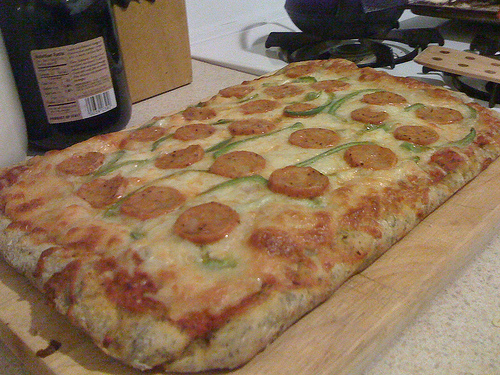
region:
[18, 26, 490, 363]
tasty pizza on board.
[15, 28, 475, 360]
delicious pizza ready to eat.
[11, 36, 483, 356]
flavorful pizza ready to eat.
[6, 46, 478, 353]
large pizza ready for consumption.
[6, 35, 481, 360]
delightful pizza ready to eat.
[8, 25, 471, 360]
full size pizza on board.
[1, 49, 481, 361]
full size delicious pizza.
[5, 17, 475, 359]
tasty pizza all ready to eat.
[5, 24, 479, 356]
big cheesy pizza ready for eating.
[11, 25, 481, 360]
big flavorful pizza for eating.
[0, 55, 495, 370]
A deep dish delicious looking homemade pizza.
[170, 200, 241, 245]
One piece of pepperoni on the pizza.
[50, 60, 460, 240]
Twenty three delicious pieces of pepperoni.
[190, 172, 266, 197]
One piece of green pepper.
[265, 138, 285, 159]
The cheese laying on the pizza.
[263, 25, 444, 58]
Cooking fire from the stove top.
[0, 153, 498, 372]
Piece of wood underneath the deep dish pizza.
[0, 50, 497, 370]
A beautiful beige counter top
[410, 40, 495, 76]
A spatula with six holes in it.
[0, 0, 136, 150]
A bottle of liquid used for cooking.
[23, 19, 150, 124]
brown bottle of sauce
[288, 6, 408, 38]
black pan on oven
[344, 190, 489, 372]
tan wooden board on counter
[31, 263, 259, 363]
brown and tan pizza with cheese and meat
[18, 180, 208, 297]
brown and tan pizza with cheese and meat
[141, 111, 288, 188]
brown and tan pizza with cheese and meat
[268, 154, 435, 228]
brown and tan pizza with cheese and meat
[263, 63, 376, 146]
brown and tan pizza with cheese and meat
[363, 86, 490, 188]
brown and tan pizza with cheese and meat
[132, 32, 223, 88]
tan wooden block on counter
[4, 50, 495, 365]
Rectangular pizza with green peppers and sausage.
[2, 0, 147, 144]
Dark wine bottle.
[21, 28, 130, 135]
Nutrition label on a bottle.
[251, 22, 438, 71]
Gas burner with metal grate.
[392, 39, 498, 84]
Wooden spatula with holes.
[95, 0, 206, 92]
Wooden knife block.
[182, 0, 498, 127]
White oven with gas range.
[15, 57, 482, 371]
Pizza sitting on top of a wooden board.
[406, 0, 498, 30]
Metal oven tray.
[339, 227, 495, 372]
Wooden board on a kitchen counter.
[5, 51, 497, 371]
a cooked pizza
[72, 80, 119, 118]
bar code on a bottle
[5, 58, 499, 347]
a rectangle pizza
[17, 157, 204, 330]
cooked cheese on pizza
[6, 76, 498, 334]
pizza on a wood board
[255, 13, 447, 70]
a burner on a stove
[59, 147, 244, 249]
round pieces of meat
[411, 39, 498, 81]
a piece of wood with holes in it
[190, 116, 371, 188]
green sliced pieces of pepper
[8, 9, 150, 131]
a tan colored label